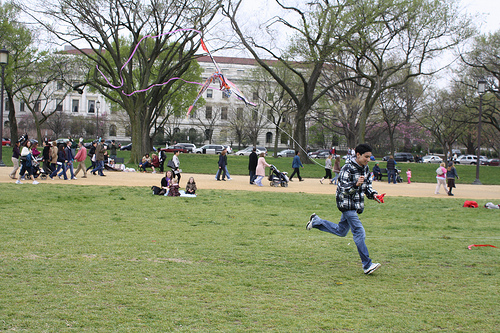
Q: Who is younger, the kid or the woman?
A: The kid is younger than the woman.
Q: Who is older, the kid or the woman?
A: The woman is older than the kid.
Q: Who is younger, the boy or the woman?
A: The boy is younger than the woman.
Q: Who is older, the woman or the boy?
A: The woman is older than the boy.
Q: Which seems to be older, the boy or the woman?
A: The woman is older than the boy.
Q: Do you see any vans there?
A: No, there are no vans.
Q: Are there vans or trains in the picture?
A: No, there are no vans or trains.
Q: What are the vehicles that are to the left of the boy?
A: The vehicles are cars.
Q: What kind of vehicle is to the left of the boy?
A: The vehicles are cars.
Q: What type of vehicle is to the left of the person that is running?
A: The vehicles are cars.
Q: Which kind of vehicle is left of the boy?
A: The vehicles are cars.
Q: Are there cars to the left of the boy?
A: Yes, there are cars to the left of the boy.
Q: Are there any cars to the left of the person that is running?
A: Yes, there are cars to the left of the boy.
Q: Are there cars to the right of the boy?
A: No, the cars are to the left of the boy.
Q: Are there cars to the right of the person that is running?
A: No, the cars are to the left of the boy.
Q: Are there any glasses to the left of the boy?
A: No, there are cars to the left of the boy.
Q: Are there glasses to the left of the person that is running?
A: No, there are cars to the left of the boy.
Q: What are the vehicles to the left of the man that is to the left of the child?
A: The vehicles are cars.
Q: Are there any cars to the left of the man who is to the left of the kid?
A: Yes, there are cars to the left of the man.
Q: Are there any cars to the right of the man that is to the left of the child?
A: No, the cars are to the left of the man.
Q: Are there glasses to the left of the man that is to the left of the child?
A: No, there are cars to the left of the man.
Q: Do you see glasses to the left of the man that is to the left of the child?
A: No, there are cars to the left of the man.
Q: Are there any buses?
A: No, there are no buses.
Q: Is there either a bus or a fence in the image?
A: No, there are no buses or fences.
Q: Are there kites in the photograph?
A: Yes, there is a kite.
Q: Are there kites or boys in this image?
A: Yes, there is a kite.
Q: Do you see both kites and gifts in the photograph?
A: No, there is a kite but no gifts.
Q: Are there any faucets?
A: No, there are no faucets.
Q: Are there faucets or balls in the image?
A: No, there are no faucets or balls.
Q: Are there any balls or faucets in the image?
A: No, there are no faucets or balls.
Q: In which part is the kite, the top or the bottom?
A: The kite is in the top of the image.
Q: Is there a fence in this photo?
A: No, there are no fences.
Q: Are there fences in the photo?
A: No, there are no fences.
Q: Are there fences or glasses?
A: No, there are no fences or glasses.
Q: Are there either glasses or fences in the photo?
A: No, there are no fences or glasses.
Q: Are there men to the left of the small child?
A: Yes, there is a man to the left of the child.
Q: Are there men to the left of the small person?
A: Yes, there is a man to the left of the child.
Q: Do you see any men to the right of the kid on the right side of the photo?
A: No, the man is to the left of the kid.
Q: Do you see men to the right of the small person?
A: No, the man is to the left of the kid.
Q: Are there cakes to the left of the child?
A: No, there is a man to the left of the child.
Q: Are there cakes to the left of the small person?
A: No, there is a man to the left of the child.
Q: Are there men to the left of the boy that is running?
A: Yes, there is a man to the left of the boy.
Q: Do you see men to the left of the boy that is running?
A: Yes, there is a man to the left of the boy.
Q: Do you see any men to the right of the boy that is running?
A: No, the man is to the left of the boy.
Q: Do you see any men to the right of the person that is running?
A: No, the man is to the left of the boy.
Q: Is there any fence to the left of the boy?
A: No, there is a man to the left of the boy.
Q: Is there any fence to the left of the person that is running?
A: No, there is a man to the left of the boy.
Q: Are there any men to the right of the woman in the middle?
A: Yes, there is a man to the right of the woman.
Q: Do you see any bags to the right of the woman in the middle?
A: No, there is a man to the right of the woman.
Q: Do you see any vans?
A: No, there are no vans.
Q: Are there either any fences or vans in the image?
A: No, there are no vans or fences.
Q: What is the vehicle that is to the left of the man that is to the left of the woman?
A: The vehicle is a car.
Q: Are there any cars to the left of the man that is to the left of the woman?
A: Yes, there is a car to the left of the man.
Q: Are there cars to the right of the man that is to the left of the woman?
A: No, the car is to the left of the man.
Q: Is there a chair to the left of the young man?
A: No, there is a car to the left of the man.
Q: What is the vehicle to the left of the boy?
A: The vehicle is a car.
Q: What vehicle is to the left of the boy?
A: The vehicle is a car.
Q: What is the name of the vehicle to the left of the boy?
A: The vehicle is a car.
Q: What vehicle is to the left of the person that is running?
A: The vehicle is a car.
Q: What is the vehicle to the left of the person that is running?
A: The vehicle is a car.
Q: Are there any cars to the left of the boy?
A: Yes, there is a car to the left of the boy.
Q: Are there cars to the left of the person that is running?
A: Yes, there is a car to the left of the boy.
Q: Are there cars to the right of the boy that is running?
A: No, the car is to the left of the boy.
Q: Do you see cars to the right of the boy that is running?
A: No, the car is to the left of the boy.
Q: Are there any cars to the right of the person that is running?
A: No, the car is to the left of the boy.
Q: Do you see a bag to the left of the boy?
A: No, there is a car to the left of the boy.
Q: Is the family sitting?
A: Yes, the family is sitting.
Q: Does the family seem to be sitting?
A: Yes, the family is sitting.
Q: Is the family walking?
A: No, the family is sitting.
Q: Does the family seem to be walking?
A: No, the family is sitting.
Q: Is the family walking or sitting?
A: The family is sitting.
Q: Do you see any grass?
A: Yes, there is grass.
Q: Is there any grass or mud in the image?
A: Yes, there is grass.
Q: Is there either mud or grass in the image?
A: Yes, there is grass.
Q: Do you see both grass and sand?
A: No, there is grass but no sand.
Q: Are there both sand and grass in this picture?
A: No, there is grass but no sand.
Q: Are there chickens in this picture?
A: No, there are no chickens.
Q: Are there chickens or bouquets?
A: No, there are no chickens or bouquets.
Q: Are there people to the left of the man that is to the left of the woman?
A: Yes, there is a person to the left of the man.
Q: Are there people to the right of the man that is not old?
A: No, the person is to the left of the man.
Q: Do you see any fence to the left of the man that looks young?
A: No, there is a person to the left of the man.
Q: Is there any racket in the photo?
A: No, there are no rackets.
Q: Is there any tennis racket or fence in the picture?
A: No, there are no rackets or fences.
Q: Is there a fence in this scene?
A: No, there are no fences.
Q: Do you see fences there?
A: No, there are no fences.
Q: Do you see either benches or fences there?
A: No, there are no fences or benches.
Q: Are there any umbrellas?
A: No, there are no umbrellas.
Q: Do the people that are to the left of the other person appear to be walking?
A: Yes, the people are walking.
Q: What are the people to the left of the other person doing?
A: The people are walking.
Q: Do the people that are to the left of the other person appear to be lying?
A: No, the people are walking.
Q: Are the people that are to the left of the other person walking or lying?
A: The people are walking.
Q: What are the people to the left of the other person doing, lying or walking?
A: The people are walking.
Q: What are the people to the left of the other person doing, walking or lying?
A: The people are walking.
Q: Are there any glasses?
A: No, there are no glasses.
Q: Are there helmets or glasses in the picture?
A: No, there are no glasses or helmets.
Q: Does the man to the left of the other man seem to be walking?
A: Yes, the man is walking.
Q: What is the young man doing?
A: The man is walking.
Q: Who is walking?
A: The man is walking.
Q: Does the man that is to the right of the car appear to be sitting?
A: No, the man is walking.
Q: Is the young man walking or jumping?
A: The man is walking.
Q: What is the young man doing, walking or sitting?
A: The man is walking.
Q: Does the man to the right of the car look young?
A: Yes, the man is young.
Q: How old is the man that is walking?
A: The man is young.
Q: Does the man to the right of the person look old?
A: No, the man is young.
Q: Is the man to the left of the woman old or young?
A: The man is young.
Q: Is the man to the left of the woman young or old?
A: The man is young.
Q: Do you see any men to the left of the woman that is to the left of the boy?
A: Yes, there is a man to the left of the woman.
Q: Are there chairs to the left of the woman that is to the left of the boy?
A: No, there is a man to the left of the woman.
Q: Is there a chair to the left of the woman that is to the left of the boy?
A: No, there is a man to the left of the woman.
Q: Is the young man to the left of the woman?
A: Yes, the man is to the left of the woman.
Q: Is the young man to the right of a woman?
A: No, the man is to the left of a woman.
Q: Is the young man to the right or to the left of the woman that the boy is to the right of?
A: The man is to the left of the woman.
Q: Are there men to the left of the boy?
A: Yes, there is a man to the left of the boy.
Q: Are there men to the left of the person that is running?
A: Yes, there is a man to the left of the boy.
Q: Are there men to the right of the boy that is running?
A: No, the man is to the left of the boy.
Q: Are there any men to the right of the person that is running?
A: No, the man is to the left of the boy.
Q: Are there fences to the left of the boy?
A: No, there is a man to the left of the boy.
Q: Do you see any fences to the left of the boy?
A: No, there is a man to the left of the boy.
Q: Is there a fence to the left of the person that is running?
A: No, there is a man to the left of the boy.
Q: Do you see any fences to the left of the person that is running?
A: No, there is a man to the left of the boy.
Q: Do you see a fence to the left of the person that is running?
A: No, there is a man to the left of the boy.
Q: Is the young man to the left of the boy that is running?
A: Yes, the man is to the left of the boy.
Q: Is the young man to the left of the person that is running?
A: Yes, the man is to the left of the boy.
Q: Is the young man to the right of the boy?
A: No, the man is to the left of the boy.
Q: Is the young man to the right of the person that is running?
A: No, the man is to the left of the boy.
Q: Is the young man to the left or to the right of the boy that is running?
A: The man is to the left of the boy.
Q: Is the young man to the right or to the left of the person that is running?
A: The man is to the left of the boy.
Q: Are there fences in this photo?
A: No, there are no fences.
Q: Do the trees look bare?
A: Yes, the trees are bare.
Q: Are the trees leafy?
A: No, the trees are bare.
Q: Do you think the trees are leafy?
A: No, the trees are bare.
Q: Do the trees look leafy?
A: No, the trees are bare.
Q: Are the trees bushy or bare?
A: The trees are bare.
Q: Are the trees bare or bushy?
A: The trees are bare.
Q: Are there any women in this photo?
A: Yes, there is a woman.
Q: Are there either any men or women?
A: Yes, there is a woman.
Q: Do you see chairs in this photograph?
A: No, there are no chairs.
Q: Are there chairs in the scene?
A: No, there are no chairs.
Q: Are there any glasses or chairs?
A: No, there are no chairs or glasses.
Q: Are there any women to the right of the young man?
A: Yes, there is a woman to the right of the man.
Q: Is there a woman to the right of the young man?
A: Yes, there is a woman to the right of the man.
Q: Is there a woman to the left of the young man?
A: No, the woman is to the right of the man.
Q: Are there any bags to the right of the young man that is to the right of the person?
A: No, there is a woman to the right of the man.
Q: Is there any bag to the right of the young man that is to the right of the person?
A: No, there is a woman to the right of the man.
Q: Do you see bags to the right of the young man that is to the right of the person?
A: No, there is a woman to the right of the man.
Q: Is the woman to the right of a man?
A: Yes, the woman is to the right of a man.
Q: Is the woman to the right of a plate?
A: No, the woman is to the right of a man.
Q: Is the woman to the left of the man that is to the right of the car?
A: No, the woman is to the right of the man.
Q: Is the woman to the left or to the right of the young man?
A: The woman is to the right of the man.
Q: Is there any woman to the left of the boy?
A: Yes, there is a woman to the left of the boy.